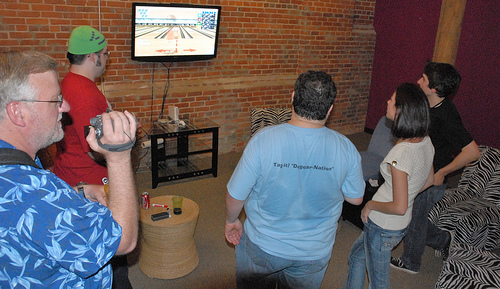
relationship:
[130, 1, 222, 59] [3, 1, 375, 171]
television on wall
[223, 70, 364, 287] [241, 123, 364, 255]
man in shirt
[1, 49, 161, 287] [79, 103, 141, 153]
man holding camera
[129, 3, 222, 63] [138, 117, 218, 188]
tv on tv stand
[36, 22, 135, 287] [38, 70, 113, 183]
man wears shirt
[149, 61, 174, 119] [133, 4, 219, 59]
cords hanging from television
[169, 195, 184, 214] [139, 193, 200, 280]
drink on table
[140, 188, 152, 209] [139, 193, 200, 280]
can on table